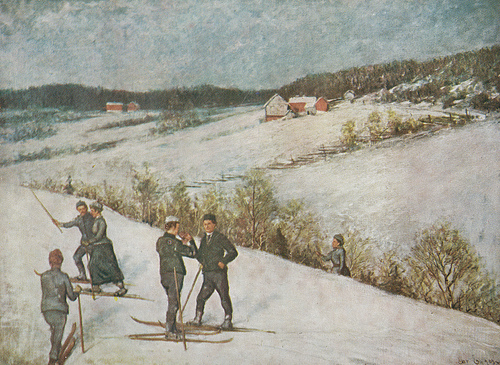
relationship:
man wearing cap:
[194, 216, 242, 317] [202, 209, 223, 225]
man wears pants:
[194, 216, 242, 317] [194, 267, 243, 311]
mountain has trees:
[415, 47, 462, 92] [404, 224, 466, 286]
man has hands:
[194, 216, 242, 317] [220, 255, 233, 271]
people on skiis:
[43, 179, 252, 345] [167, 306, 220, 351]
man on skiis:
[194, 216, 242, 317] [167, 306, 220, 351]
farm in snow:
[248, 67, 367, 134] [335, 165, 395, 196]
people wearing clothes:
[78, 199, 128, 297] [87, 220, 123, 286]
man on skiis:
[177, 212, 239, 330] [167, 306, 220, 351]